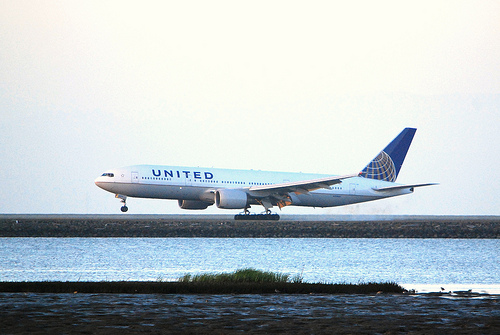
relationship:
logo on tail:
[368, 151, 412, 178] [358, 124, 418, 183]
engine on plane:
[208, 188, 251, 209] [93, 123, 455, 231]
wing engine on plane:
[208, 188, 251, 209] [93, 123, 455, 231]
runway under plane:
[2, 202, 499, 223] [93, 123, 455, 231]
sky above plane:
[0, 1, 498, 210] [93, 123, 455, 231]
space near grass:
[3, 292, 499, 330] [158, 263, 311, 287]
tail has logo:
[358, 124, 418, 183] [368, 151, 412, 178]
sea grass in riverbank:
[158, 263, 311, 287] [2, 276, 494, 305]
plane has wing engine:
[93, 123, 455, 231] [208, 188, 251, 209]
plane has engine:
[93, 123, 455, 231] [208, 188, 251, 209]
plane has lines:
[93, 123, 455, 231] [360, 146, 395, 186]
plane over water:
[93, 123, 455, 231] [3, 232, 497, 302]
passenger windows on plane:
[138, 173, 275, 187] [93, 125, 423, 219]